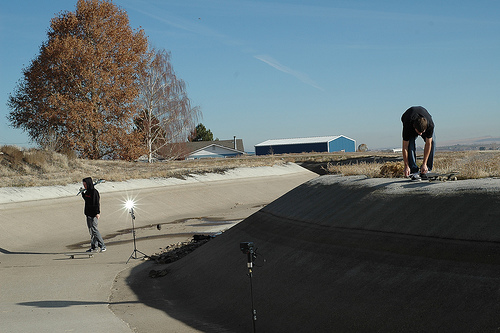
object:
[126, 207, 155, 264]
part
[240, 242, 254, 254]
camera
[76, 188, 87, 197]
part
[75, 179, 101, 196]
board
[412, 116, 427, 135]
head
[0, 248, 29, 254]
part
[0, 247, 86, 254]
shadow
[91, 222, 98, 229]
part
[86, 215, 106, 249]
trousers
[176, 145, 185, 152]
part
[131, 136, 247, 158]
roof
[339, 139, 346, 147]
portion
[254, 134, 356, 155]
building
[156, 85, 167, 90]
part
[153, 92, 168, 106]
branch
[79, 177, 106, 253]
skateboarder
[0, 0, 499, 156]
sky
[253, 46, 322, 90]
clouds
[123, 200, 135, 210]
light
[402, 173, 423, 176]
rod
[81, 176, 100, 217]
hoodie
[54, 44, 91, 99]
leaves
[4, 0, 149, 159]
tree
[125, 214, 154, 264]
tripod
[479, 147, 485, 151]
house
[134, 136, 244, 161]
house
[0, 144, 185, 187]
hill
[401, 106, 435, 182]
man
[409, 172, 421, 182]
shoe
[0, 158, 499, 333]
skate park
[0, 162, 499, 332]
asphalt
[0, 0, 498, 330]
background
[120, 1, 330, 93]
line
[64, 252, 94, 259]
skateboard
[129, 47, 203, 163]
tree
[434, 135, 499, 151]
hills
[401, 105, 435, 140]
shirt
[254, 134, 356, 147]
roof